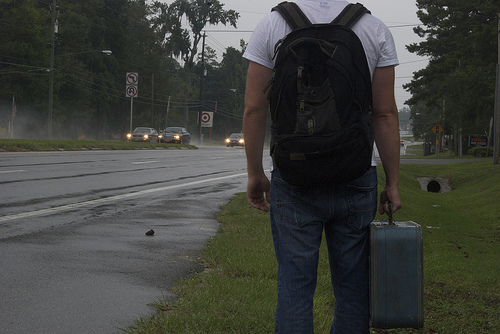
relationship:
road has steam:
[1, 131, 424, 225] [2, 98, 270, 149]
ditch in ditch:
[411, 174, 456, 194] [411, 165, 490, 267]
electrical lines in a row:
[2, 55, 259, 123] [1, 56, 246, 124]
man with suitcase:
[235, 3, 407, 331] [375, 220, 423, 323]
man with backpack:
[235, 3, 407, 331] [268, 1, 374, 191]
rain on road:
[2, 2, 420, 138] [1, 131, 424, 225]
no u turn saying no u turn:
[124, 86, 139, 99] [124, 86, 139, 99]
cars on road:
[125, 124, 245, 152] [1, 131, 424, 225]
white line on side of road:
[0, 167, 274, 230] [1, 131, 424, 225]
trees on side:
[0, 3, 247, 141] [4, 135, 281, 146]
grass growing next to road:
[244, 277, 273, 303] [29, 153, 138, 263]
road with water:
[1, 131, 414, 333] [59, 194, 74, 200]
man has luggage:
[235, 3, 407, 331] [369, 194, 435, 330]